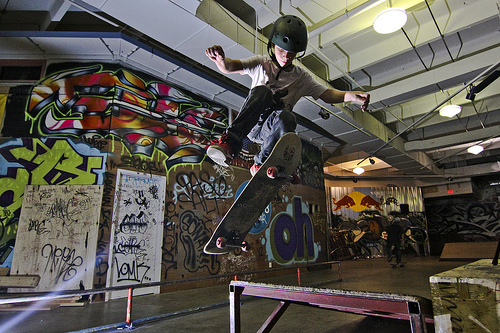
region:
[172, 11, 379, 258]
A boy jumping on a skateboard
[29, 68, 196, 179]
A wall with multi-colored graffiti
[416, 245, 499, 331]
A wooden skateboard ramp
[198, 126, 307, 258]
A skateboard with red wheels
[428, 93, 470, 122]
A light on the ceiling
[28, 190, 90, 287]
Black graffiti writing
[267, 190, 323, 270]
Blue graffiti that says "oh"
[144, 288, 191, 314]
A gray concrete ground surface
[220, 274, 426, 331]
A metal skateboard ramp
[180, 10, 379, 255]
A boy skateboarding wearing a black helmet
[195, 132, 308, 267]
a skate board in mid air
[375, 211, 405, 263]
a person walking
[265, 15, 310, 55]
a black skate boarding helmet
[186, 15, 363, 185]
a young kid doing tricks on a skateboard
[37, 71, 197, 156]
some very good graffiti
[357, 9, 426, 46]
a ceiling light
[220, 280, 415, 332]
a small ramp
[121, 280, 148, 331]
a small rail gate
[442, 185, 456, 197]
a small red light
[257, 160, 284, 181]
some red skateboard wheels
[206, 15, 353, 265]
Boy jumping on his skateboard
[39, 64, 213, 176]
Walls in bakcgorund are spray-painted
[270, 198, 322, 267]
Blud word "oh" on back wall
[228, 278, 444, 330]
Skateboard ramp is red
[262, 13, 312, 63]
Boy wearing a black helmet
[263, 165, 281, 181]
Wheels on skateboard are red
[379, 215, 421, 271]
Another boy in the background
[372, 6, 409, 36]
Light fixtures overhead are on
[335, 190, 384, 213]
Red and yellow logo on back wall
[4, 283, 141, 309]
Skateboard rails are grey and red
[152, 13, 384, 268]
a boy jumping a skateboard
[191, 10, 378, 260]
a boy doing a trick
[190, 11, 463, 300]
a boy jumping his board on a rail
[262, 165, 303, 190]
the rubber wheels of a skateboard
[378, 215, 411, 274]
a man riding his skateboard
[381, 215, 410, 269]
a man wearing black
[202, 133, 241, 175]
a red and white tennis shoe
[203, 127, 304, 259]
a worn wooden skateboard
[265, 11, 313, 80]
a boy wearing a helmet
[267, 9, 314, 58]
a black skateboarding helmet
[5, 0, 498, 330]
a skater doing tricks indoors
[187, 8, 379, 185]
skater in the air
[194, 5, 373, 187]
skater wears agreen helmet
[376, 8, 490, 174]
three lights on a ceiling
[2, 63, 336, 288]
graffiti painted on a wall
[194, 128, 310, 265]
skateboard is in the air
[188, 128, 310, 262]
skateboard has red wheels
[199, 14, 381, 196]
skater is crouched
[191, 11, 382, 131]
skater has extended arms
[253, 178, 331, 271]
word Oh on wall